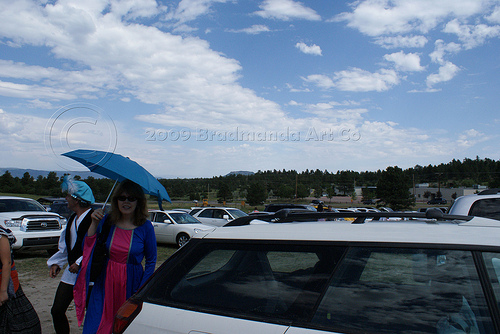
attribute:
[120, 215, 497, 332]
car — white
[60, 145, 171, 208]
umbrella — blue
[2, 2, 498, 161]
sky — blue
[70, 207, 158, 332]
dress — blue, pink 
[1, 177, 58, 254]
pickup — white 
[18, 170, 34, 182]
tree — green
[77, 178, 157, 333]
woman — blue 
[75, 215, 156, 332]
dress — pink 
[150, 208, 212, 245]
coupe — white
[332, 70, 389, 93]
cloud — white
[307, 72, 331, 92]
cloud — white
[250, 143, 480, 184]
trees — green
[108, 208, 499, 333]
vehicle — white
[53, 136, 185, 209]
umbrella — large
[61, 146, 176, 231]
umbrella — blue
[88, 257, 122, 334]
dress — red and blue